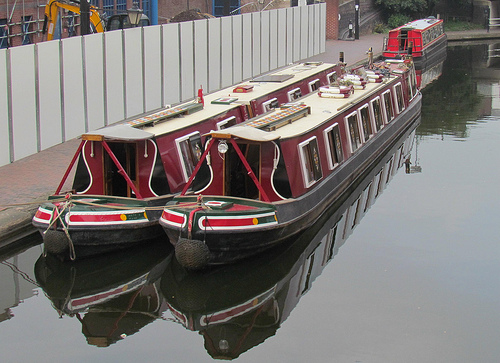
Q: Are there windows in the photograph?
A: Yes, there is a window.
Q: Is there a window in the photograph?
A: Yes, there is a window.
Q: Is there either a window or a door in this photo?
A: Yes, there is a window.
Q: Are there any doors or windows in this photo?
A: Yes, there is a window.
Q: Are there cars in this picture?
A: No, there are no cars.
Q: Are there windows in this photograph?
A: Yes, there is a window.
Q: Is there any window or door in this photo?
A: Yes, there is a window.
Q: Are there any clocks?
A: No, there are no clocks.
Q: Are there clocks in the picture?
A: No, there are no clocks.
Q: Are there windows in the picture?
A: Yes, there is a window.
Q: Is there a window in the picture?
A: Yes, there is a window.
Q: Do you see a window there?
A: Yes, there is a window.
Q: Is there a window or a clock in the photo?
A: Yes, there is a window.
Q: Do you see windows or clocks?
A: Yes, there is a window.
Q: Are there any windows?
A: Yes, there is a window.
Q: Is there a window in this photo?
A: Yes, there is a window.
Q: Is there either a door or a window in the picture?
A: Yes, there is a window.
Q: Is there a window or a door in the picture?
A: Yes, there is a window.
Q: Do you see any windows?
A: Yes, there is a window.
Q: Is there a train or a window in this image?
A: Yes, there is a window.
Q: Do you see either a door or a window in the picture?
A: Yes, there is a window.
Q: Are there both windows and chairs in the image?
A: No, there is a window but no chairs.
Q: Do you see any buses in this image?
A: No, there are no buses.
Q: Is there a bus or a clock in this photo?
A: No, there are no buses or clocks.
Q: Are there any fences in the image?
A: Yes, there is a fence.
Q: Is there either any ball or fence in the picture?
A: Yes, there is a fence.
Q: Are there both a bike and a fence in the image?
A: No, there is a fence but no bikes.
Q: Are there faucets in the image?
A: No, there are no faucets.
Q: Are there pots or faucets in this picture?
A: No, there are no faucets or pots.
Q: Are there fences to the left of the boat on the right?
A: Yes, there is a fence to the left of the boat.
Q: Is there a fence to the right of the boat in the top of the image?
A: No, the fence is to the left of the boat.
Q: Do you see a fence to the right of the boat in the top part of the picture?
A: No, the fence is to the left of the boat.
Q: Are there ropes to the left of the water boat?
A: No, there is a fence to the left of the boat.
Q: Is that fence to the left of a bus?
A: No, the fence is to the left of the boat.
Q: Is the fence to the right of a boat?
A: No, the fence is to the left of a boat.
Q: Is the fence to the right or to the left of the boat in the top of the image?
A: The fence is to the left of the boat.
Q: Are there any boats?
A: Yes, there is a boat.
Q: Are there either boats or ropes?
A: Yes, there is a boat.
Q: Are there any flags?
A: No, there are no flags.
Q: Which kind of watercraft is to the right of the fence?
A: The watercraft is a boat.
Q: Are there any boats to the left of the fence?
A: No, the boat is to the right of the fence.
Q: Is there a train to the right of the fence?
A: No, there is a boat to the right of the fence.